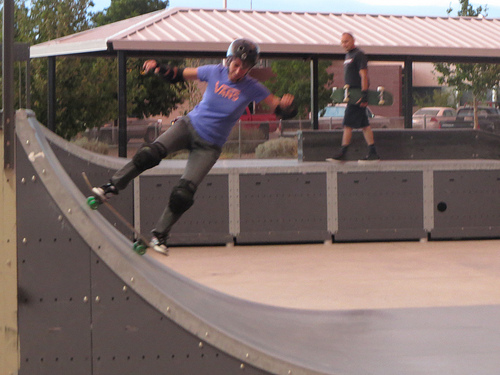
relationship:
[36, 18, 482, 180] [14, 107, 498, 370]
pavillion next to skateboard ramp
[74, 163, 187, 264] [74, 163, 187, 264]
board with board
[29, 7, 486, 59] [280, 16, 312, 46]
roof with stripes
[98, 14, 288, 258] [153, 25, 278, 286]
person wearing girl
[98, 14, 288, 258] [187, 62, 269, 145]
person wearing blue shirt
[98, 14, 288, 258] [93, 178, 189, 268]
person wearing shoes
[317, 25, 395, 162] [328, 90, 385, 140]
person wearing shorts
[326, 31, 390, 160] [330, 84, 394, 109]
man holding skateboard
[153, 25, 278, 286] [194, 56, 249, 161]
girl in shirt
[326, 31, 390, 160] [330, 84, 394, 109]
man walking with skateboard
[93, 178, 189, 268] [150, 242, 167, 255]
shoes with soles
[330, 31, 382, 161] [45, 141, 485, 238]
man walking on edge of wall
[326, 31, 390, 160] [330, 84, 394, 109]
man carrying skateboard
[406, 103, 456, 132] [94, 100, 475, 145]
white car in parking lot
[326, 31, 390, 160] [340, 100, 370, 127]
man wearing shorts